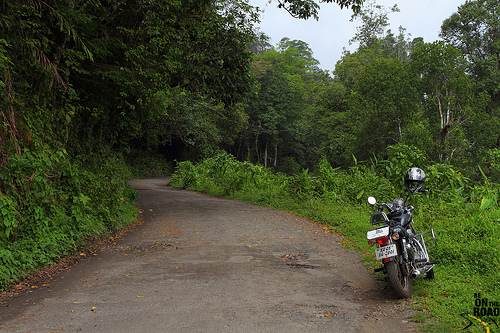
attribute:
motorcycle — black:
[361, 197, 445, 297]